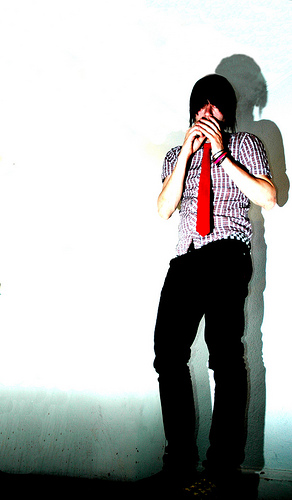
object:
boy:
[152, 74, 276, 499]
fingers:
[188, 116, 221, 152]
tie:
[196, 142, 211, 237]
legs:
[152, 259, 202, 433]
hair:
[189, 74, 237, 134]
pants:
[153, 239, 247, 465]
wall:
[19, 1, 124, 143]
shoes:
[178, 470, 243, 498]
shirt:
[162, 132, 273, 257]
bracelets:
[211, 147, 229, 167]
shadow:
[188, 53, 291, 500]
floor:
[1, 400, 134, 500]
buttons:
[190, 162, 202, 235]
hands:
[184, 117, 224, 153]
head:
[187, 72, 237, 132]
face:
[195, 100, 224, 124]